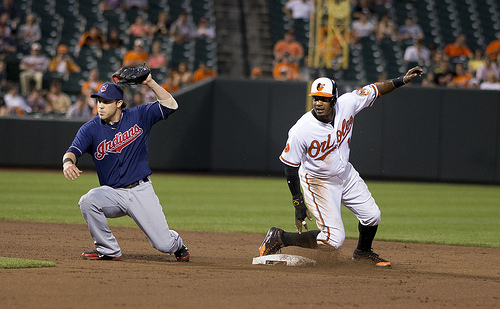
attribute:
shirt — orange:
[166, 85, 169, 88]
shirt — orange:
[493, 44, 498, 50]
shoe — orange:
[263, 226, 285, 256]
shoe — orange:
[359, 250, 383, 265]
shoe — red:
[83, 253, 99, 260]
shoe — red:
[177, 255, 189, 261]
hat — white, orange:
[314, 80, 330, 95]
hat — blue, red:
[97, 85, 115, 98]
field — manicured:
[188, 181, 260, 224]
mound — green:
[108, 270, 300, 309]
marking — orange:
[114, 78, 118, 81]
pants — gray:
[92, 192, 148, 211]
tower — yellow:
[319, 3, 349, 68]